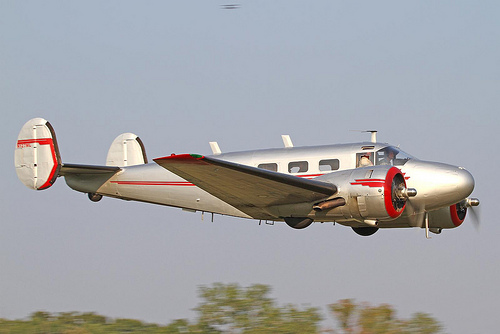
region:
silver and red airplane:
[8, 111, 490, 248]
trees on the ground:
[0, 284, 453, 332]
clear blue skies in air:
[2, 0, 494, 115]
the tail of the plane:
[16, 116, 62, 193]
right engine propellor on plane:
[385, 173, 411, 218]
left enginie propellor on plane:
[452, 190, 478, 228]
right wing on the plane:
[158, 149, 330, 210]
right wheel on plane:
[283, 216, 319, 229]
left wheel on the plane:
[346, 224, 387, 242]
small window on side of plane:
[318, 158, 345, 173]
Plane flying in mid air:
[2, 88, 493, 219]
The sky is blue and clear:
[22, 12, 230, 119]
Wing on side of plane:
[137, 133, 346, 218]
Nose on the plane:
[377, 111, 496, 251]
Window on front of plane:
[363, 125, 412, 173]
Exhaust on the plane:
[297, 169, 362, 214]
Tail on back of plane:
[11, 101, 130, 192]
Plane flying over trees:
[27, 228, 422, 331]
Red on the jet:
[363, 170, 423, 227]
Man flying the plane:
[361, 123, 438, 175]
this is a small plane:
[214, 136, 482, 246]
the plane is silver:
[427, 199, 477, 224]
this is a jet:
[328, 107, 385, 220]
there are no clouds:
[250, 55, 349, 140]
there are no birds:
[183, 6, 302, 113]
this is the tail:
[26, 144, 86, 178]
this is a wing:
[167, 177, 315, 201]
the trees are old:
[219, 284, 277, 319]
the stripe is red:
[103, 146, 263, 268]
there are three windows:
[260, 112, 325, 251]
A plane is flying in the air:
[9, 106, 492, 251]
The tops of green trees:
[1, 276, 444, 331]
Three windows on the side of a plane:
[256, 153, 344, 179]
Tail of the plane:
[10, 113, 150, 210]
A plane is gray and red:
[10, 110, 489, 246]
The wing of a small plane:
[152, 149, 342, 227]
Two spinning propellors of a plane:
[391, 163, 488, 234]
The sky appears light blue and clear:
[2, 2, 498, 332]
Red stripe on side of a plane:
[106, 170, 199, 191]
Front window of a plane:
[353, 137, 416, 171]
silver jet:
[7, 94, 492, 243]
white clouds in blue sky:
[15, 27, 51, 57]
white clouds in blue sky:
[316, 11, 374, 88]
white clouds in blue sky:
[394, 41, 446, 110]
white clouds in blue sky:
[205, 36, 252, 75]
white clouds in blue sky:
[47, 235, 99, 266]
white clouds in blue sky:
[158, 59, 227, 89]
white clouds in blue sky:
[47, 36, 107, 80]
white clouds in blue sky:
[342, 238, 380, 274]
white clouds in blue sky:
[155, 225, 208, 272]